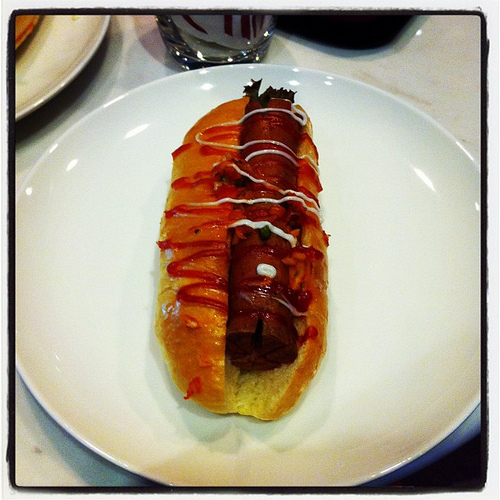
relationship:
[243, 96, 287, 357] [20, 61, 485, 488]
dog on a plate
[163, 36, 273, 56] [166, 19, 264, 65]
bottom of glass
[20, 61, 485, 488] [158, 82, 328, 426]
plate with food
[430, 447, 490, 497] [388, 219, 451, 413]
shadow underneath plate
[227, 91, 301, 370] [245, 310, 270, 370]
dog has cuts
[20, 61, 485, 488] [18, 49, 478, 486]
plate on table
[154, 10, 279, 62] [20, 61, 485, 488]
glass near plate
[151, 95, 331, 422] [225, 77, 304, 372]
bun with hot dog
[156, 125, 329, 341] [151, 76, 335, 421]
ketchup drizzled on bun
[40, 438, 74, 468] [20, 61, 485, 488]
table under plate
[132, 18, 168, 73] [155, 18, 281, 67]
shadow from glass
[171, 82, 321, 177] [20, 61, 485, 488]
portion of plate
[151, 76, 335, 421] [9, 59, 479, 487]
bun on a white plate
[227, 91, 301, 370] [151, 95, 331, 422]
dog in a bun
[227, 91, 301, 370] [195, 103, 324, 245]
dog with mayonaise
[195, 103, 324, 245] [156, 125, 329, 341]
mayonaise and ketchup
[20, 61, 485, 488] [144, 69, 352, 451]
plate with food